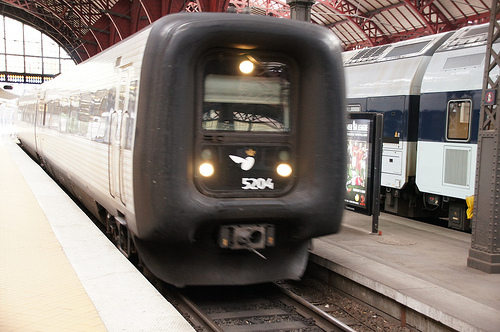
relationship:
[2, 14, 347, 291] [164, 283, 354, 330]
train on tracks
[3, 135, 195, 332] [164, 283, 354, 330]
platform beside tracks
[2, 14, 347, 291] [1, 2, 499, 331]
train in station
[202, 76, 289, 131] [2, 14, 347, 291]
window on train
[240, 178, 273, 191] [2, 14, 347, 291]
number on train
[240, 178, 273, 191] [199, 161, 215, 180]
number under light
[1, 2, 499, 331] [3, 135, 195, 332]
station has platform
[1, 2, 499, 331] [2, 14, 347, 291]
station has train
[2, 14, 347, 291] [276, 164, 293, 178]
train has light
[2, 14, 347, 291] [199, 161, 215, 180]
train has light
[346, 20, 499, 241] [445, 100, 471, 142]
train has window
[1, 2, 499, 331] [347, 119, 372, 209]
station has poster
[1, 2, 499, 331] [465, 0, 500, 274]
station has support beam